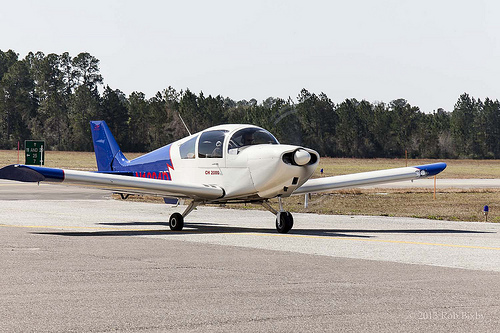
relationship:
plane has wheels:
[102, 122, 321, 213] [164, 207, 309, 240]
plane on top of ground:
[102, 122, 321, 213] [130, 249, 262, 280]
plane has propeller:
[102, 122, 321, 213] [290, 149, 316, 165]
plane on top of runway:
[102, 122, 321, 213] [317, 216, 394, 301]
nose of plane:
[275, 136, 325, 190] [102, 122, 321, 213]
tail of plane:
[86, 108, 128, 159] [102, 122, 321, 213]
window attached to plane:
[197, 123, 223, 158] [102, 122, 321, 213]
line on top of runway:
[317, 231, 397, 248] [317, 216, 394, 301]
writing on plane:
[202, 172, 221, 179] [102, 122, 321, 213]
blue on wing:
[89, 140, 146, 181] [1, 156, 176, 186]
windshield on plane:
[221, 131, 279, 148] [102, 122, 321, 213]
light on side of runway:
[479, 194, 494, 218] [317, 216, 394, 301]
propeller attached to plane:
[290, 149, 316, 165] [102, 122, 321, 213]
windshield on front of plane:
[221, 131, 279, 148] [102, 122, 321, 213]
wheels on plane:
[164, 207, 309, 240] [0, 114, 446, 233]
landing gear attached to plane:
[202, 195, 273, 241] [102, 122, 321, 213]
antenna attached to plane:
[170, 109, 198, 137] [0, 114, 446, 233]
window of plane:
[197, 123, 223, 158] [102, 122, 321, 213]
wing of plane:
[1, 156, 176, 186] [0, 114, 446, 233]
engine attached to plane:
[155, 191, 217, 205] [102, 122, 321, 213]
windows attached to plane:
[149, 140, 249, 173] [102, 122, 321, 213]